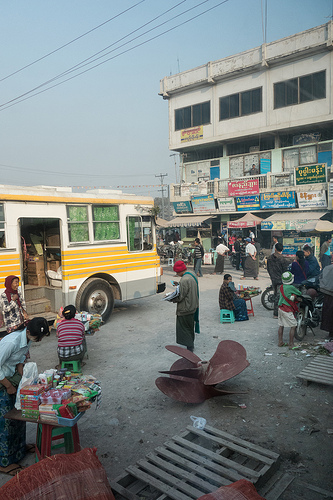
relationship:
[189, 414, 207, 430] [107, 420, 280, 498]
item on crate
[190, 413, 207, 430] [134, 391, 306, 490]
item on crate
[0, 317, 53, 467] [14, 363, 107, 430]
she looking at items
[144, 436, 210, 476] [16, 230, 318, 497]
pallet on ground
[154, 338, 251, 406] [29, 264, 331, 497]
fan blade on ground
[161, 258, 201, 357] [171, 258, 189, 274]
man wearing cap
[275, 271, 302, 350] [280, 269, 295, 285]
child wearing hat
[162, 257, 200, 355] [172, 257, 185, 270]
man wearing hat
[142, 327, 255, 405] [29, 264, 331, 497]
propeller on ground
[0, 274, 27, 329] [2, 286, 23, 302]
person wearing scarf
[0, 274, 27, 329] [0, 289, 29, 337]
person wearing shirt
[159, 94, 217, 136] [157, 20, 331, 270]
window on a building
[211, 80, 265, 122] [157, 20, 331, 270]
window on a building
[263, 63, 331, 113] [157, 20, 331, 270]
window on a building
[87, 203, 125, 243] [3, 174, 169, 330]
curtains on a bus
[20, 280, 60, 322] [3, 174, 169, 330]
steps on bus